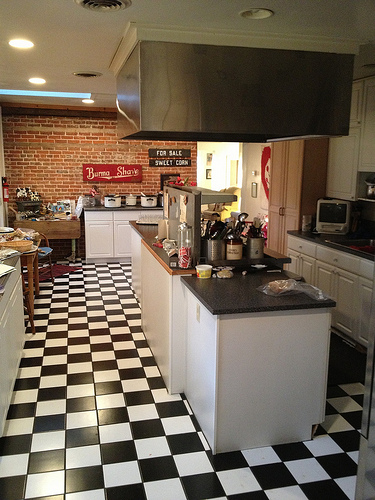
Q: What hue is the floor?
A: Black and white.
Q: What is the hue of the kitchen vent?
A: Silver.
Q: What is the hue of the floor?
A: Black and white.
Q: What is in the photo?
A: Kitchen.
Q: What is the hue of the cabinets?
A: White.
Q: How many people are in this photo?
A: Zero.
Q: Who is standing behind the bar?
A: No one.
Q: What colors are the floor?
A: Black and White.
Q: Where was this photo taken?
A: Cafe shop.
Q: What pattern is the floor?
A: Checkered.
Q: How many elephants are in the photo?
A: None.